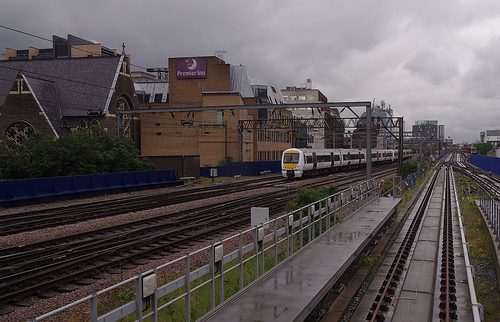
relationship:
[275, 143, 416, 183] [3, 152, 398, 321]
train on tracks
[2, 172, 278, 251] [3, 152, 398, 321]
gravel near tracks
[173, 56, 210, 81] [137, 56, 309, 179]
sign on building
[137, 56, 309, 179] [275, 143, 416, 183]
building near train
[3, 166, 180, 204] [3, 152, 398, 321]
barrier near tracks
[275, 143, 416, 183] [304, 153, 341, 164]
train has windows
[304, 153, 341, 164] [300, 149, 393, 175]
windows on side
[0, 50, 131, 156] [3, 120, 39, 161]
building has window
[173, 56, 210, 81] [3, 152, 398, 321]
sign above railway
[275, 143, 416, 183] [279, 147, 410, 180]
train for passangers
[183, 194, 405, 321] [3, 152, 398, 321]
bench beside tracks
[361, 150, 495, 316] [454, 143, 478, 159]
tracks for trolley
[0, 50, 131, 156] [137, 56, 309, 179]
church beside hotel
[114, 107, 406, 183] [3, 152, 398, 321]
signal above tracks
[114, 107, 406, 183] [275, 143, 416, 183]
signal for train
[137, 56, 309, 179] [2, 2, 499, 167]
bulding in background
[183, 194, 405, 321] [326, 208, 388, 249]
bench with puddles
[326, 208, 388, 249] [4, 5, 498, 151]
puddles after rain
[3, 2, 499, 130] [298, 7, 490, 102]
sky has clouds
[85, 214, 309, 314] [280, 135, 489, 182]
grass between trains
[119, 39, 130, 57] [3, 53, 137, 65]
cross on top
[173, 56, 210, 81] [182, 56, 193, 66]
graphic of star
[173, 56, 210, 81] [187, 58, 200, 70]
graphic of moon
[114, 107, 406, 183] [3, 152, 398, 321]
spans across track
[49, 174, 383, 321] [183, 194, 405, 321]
railing along platform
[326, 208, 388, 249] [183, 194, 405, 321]
puddles on platform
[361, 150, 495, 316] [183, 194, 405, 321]
track beside platform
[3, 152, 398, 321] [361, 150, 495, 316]
traditional near modern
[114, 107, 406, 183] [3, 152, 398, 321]
structures over tracks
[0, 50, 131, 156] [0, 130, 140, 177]
church behind trees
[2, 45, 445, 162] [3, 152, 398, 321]
buildings beside tracks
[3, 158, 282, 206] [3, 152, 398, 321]
wall beside tracks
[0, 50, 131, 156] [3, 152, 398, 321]
church beside track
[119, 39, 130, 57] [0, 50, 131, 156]
cross on church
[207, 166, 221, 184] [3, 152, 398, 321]
sign beside tracks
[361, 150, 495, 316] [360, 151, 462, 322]
concrete below tracks